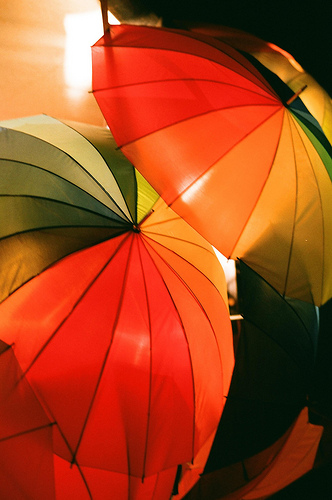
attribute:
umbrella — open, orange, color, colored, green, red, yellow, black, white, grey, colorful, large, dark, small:
[92, 23, 331, 306]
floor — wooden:
[184, 409, 328, 499]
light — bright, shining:
[66, 14, 121, 94]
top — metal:
[285, 83, 304, 106]